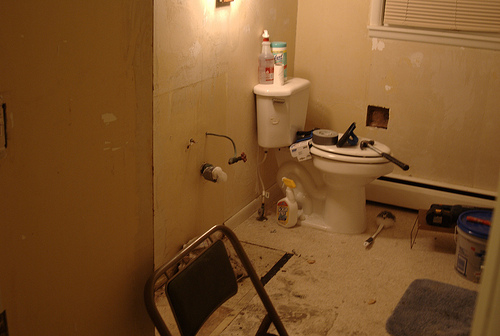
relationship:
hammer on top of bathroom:
[359, 138, 411, 171] [1, 0, 500, 334]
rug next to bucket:
[386, 279, 479, 335] [454, 224, 488, 283]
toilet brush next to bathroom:
[365, 209, 396, 248] [1, 0, 500, 334]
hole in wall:
[366, 104, 390, 130] [294, 0, 500, 193]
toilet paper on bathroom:
[274, 62, 286, 88] [1, 0, 500, 334]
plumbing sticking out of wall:
[200, 133, 248, 183] [153, 1, 300, 280]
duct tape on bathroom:
[314, 127, 340, 146] [1, 0, 500, 334]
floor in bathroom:
[155, 191, 481, 335] [1, 1, 500, 335]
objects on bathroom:
[258, 28, 411, 173] [1, 0, 500, 334]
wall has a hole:
[294, 0, 500, 193] [366, 104, 390, 130]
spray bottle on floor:
[275, 174, 302, 227] [155, 191, 481, 335]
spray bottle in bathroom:
[275, 174, 302, 227] [1, 1, 500, 335]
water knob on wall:
[241, 151, 248, 162] [153, 1, 300, 280]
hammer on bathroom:
[359, 138, 411, 171] [1, 0, 500, 334]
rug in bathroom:
[386, 279, 479, 335] [1, 1, 500, 335]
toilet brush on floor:
[365, 209, 396, 248] [155, 191, 481, 335]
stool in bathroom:
[144, 223, 291, 335] [1, 1, 500, 335]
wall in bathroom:
[294, 0, 500, 193] [1, 1, 500, 335]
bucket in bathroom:
[454, 224, 488, 283] [1, 1, 500, 335]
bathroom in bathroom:
[1, 0, 500, 334] [1, 1, 500, 335]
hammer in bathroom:
[359, 138, 411, 171] [1, 1, 500, 335]